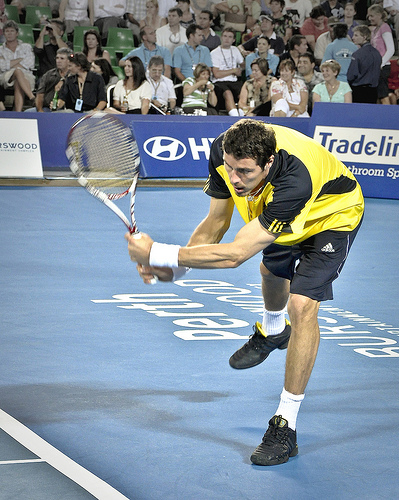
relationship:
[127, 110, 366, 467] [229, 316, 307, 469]
man wearing shoes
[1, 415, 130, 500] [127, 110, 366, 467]
line near man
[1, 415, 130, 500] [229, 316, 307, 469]
line near shoes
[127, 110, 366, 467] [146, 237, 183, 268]
man wearing wrist band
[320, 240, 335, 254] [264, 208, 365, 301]
logo across shorts